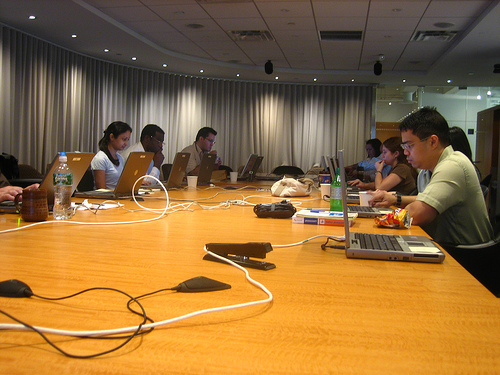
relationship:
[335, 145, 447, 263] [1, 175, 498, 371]
lap top sits on table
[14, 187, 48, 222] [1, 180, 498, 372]
cup sits on desk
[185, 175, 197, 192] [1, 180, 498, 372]
cup sits on desk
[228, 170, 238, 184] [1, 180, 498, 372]
cup sits on desk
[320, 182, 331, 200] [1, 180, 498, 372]
cup sits on desk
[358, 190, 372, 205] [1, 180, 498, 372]
cup sits on desk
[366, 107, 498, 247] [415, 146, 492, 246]
man wearing shirt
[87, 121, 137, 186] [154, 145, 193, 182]
woman using laptop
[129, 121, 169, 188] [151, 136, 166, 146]
man wearing eyeglasses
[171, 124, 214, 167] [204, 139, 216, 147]
man wearing eyeglasses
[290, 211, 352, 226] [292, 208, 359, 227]
book stacked beneath book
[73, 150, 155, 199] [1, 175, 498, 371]
lap top on table